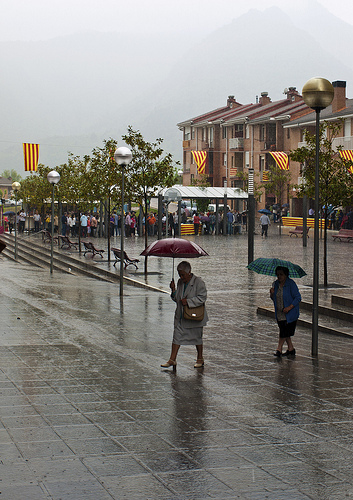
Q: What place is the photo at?
A: It is at the park.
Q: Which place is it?
A: It is a park.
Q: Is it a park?
A: Yes, it is a park.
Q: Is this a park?
A: Yes, it is a park.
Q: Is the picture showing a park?
A: Yes, it is showing a park.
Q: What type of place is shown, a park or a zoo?
A: It is a park.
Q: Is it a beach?
A: No, it is a park.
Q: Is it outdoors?
A: Yes, it is outdoors.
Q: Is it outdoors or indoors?
A: It is outdoors.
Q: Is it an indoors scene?
A: No, it is outdoors.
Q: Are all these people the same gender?
A: Yes, all the people are female.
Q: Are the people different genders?
A: No, all the people are female.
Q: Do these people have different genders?
A: No, all the people are female.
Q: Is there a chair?
A: Yes, there is a chair.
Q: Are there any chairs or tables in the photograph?
A: Yes, there is a chair.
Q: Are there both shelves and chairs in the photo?
A: No, there is a chair but no shelves.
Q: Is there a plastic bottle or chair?
A: Yes, there is a plastic chair.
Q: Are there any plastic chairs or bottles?
A: Yes, there is a plastic chair.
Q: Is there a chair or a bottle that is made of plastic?
A: Yes, the chair is made of plastic.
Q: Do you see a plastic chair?
A: Yes, there is a chair that is made of plastic.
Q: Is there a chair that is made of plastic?
A: Yes, there is a chair that is made of plastic.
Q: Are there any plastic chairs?
A: Yes, there is a chair that is made of plastic.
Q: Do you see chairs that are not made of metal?
A: Yes, there is a chair that is made of plastic.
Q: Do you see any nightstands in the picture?
A: No, there are no nightstands.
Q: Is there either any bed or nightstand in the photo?
A: No, there are no nightstands or beds.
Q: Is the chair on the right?
A: Yes, the chair is on the right of the image.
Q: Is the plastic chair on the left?
A: No, the chair is on the right of the image.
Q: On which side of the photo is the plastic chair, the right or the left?
A: The chair is on the right of the image.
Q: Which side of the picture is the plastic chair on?
A: The chair is on the right of the image.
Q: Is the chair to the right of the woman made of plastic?
A: Yes, the chair is made of plastic.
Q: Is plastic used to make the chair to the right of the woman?
A: Yes, the chair is made of plastic.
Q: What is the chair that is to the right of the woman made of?
A: The chair is made of plastic.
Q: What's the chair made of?
A: The chair is made of plastic.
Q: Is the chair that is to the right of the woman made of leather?
A: No, the chair is made of plastic.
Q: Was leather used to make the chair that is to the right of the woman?
A: No, the chair is made of plastic.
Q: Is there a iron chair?
A: No, there is a chair but it is made of plastic.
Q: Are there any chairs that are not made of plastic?
A: No, there is a chair but it is made of plastic.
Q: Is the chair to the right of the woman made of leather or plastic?
A: The chair is made of plastic.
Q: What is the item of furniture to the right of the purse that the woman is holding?
A: The piece of furniture is a chair.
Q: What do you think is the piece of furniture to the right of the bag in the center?
A: The piece of furniture is a chair.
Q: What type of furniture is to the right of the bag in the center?
A: The piece of furniture is a chair.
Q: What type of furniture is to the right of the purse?
A: The piece of furniture is a chair.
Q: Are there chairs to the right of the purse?
A: Yes, there is a chair to the right of the purse.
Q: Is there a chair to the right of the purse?
A: Yes, there is a chair to the right of the purse.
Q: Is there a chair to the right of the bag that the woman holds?
A: Yes, there is a chair to the right of the purse.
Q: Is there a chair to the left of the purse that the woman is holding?
A: No, the chair is to the right of the purse.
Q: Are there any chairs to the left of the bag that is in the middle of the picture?
A: No, the chair is to the right of the purse.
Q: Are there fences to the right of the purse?
A: No, there is a chair to the right of the purse.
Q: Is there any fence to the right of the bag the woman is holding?
A: No, there is a chair to the right of the purse.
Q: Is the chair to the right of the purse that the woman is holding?
A: Yes, the chair is to the right of the purse.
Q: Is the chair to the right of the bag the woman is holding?
A: Yes, the chair is to the right of the purse.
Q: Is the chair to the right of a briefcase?
A: No, the chair is to the right of the purse.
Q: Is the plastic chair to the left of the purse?
A: No, the chair is to the right of the purse.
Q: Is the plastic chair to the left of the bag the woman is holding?
A: No, the chair is to the right of the purse.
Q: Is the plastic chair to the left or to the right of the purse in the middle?
A: The chair is to the right of the purse.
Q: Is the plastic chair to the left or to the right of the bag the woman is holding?
A: The chair is to the right of the purse.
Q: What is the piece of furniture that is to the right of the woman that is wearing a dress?
A: The piece of furniture is a chair.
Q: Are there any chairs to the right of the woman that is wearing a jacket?
A: Yes, there is a chair to the right of the woman.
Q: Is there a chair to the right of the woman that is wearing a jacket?
A: Yes, there is a chair to the right of the woman.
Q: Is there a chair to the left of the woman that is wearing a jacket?
A: No, the chair is to the right of the woman.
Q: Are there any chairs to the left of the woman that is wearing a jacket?
A: No, the chair is to the right of the woman.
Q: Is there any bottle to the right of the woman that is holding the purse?
A: No, there is a chair to the right of the woman.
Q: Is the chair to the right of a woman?
A: Yes, the chair is to the right of a woman.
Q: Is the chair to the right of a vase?
A: No, the chair is to the right of a woman.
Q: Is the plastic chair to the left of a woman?
A: No, the chair is to the right of a woman.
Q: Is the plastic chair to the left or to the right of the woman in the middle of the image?
A: The chair is to the right of the woman.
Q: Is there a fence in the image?
A: No, there are no fences.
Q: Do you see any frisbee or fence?
A: No, there are no fences or frisbees.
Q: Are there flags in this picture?
A: Yes, there is a flag.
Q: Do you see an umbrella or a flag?
A: Yes, there is a flag.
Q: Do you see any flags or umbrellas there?
A: Yes, there is a flag.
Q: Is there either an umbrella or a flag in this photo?
A: Yes, there is a flag.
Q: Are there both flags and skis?
A: No, there is a flag but no skis.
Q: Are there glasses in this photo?
A: No, there are no glasses.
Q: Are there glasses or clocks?
A: No, there are no glasses or clocks.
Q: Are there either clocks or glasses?
A: No, there are no glasses or clocks.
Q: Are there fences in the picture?
A: No, there are no fences.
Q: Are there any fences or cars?
A: No, there are no fences or cars.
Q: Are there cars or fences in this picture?
A: No, there are no fences or cars.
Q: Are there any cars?
A: No, there are no cars.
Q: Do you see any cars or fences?
A: No, there are no cars or fences.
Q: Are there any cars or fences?
A: No, there are no cars or fences.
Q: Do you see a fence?
A: No, there are no fences.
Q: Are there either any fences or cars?
A: No, there are no fences or cars.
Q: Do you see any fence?
A: No, there are no fences.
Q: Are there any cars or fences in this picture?
A: No, there are no fences or cars.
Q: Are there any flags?
A: Yes, there is a flag.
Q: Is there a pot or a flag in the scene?
A: Yes, there is a flag.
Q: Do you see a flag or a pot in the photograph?
A: Yes, there is a flag.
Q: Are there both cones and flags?
A: No, there is a flag but no cones.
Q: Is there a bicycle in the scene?
A: No, there are no bicycles.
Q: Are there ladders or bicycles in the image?
A: No, there are no bicycles or ladders.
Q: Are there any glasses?
A: No, there are no glasses.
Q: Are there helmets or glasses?
A: No, there are no glasses or helmets.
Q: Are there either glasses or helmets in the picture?
A: No, there are no glasses or helmets.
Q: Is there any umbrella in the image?
A: Yes, there is an umbrella.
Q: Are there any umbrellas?
A: Yes, there is an umbrella.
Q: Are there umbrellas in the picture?
A: Yes, there is an umbrella.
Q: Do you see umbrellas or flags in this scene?
A: Yes, there is an umbrella.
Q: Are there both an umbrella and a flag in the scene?
A: Yes, there are both an umbrella and a flag.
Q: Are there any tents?
A: No, there are no tents.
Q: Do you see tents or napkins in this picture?
A: No, there are no tents or napkins.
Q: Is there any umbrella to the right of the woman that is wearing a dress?
A: Yes, there is an umbrella to the right of the woman.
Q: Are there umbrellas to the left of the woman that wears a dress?
A: No, the umbrella is to the right of the woman.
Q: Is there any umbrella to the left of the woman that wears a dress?
A: No, the umbrella is to the right of the woman.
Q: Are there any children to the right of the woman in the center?
A: No, there is an umbrella to the right of the woman.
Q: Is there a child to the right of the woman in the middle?
A: No, there is an umbrella to the right of the woman.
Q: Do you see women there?
A: Yes, there is a woman.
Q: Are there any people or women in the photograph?
A: Yes, there is a woman.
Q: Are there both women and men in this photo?
A: No, there is a woman but no men.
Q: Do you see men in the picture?
A: No, there are no men.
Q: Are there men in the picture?
A: No, there are no men.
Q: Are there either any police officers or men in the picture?
A: No, there are no men or police officers.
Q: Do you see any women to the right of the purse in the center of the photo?
A: Yes, there is a woman to the right of the purse.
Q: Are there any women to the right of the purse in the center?
A: Yes, there is a woman to the right of the purse.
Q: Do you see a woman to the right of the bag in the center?
A: Yes, there is a woman to the right of the purse.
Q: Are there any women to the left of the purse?
A: No, the woman is to the right of the purse.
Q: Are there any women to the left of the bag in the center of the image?
A: No, the woman is to the right of the purse.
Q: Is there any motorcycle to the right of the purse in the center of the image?
A: No, there is a woman to the right of the purse.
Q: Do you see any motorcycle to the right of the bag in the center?
A: No, there is a woman to the right of the purse.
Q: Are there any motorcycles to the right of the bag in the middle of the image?
A: No, there is a woman to the right of the purse.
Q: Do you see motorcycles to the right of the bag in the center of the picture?
A: No, there is a woman to the right of the purse.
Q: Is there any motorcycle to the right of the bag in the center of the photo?
A: No, there is a woman to the right of the purse.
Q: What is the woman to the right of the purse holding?
A: The woman is holding the umbrella.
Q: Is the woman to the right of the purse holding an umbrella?
A: Yes, the woman is holding an umbrella.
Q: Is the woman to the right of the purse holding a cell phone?
A: No, the woman is holding an umbrella.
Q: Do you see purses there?
A: Yes, there is a purse.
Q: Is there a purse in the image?
A: Yes, there is a purse.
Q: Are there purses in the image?
A: Yes, there is a purse.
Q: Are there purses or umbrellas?
A: Yes, there is a purse.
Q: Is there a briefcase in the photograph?
A: No, there are no briefcases.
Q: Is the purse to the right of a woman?
A: No, the purse is to the left of a woman.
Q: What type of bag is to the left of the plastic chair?
A: The bag is a purse.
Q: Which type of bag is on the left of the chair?
A: The bag is a purse.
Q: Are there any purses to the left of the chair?
A: Yes, there is a purse to the left of the chair.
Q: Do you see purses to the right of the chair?
A: No, the purse is to the left of the chair.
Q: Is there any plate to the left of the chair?
A: No, there is a purse to the left of the chair.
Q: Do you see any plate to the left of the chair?
A: No, there is a purse to the left of the chair.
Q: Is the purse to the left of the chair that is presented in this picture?
A: Yes, the purse is to the left of the chair.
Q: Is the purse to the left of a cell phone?
A: No, the purse is to the left of the chair.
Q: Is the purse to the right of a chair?
A: No, the purse is to the left of a chair.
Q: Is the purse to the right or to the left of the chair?
A: The purse is to the left of the chair.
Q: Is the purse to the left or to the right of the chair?
A: The purse is to the left of the chair.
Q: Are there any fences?
A: No, there are no fences.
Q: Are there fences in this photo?
A: No, there are no fences.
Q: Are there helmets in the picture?
A: No, there are no helmets.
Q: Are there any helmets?
A: No, there are no helmets.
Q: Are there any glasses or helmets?
A: No, there are no helmets or glasses.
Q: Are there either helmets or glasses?
A: No, there are no helmets or glasses.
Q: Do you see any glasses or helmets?
A: No, there are no helmets or glasses.